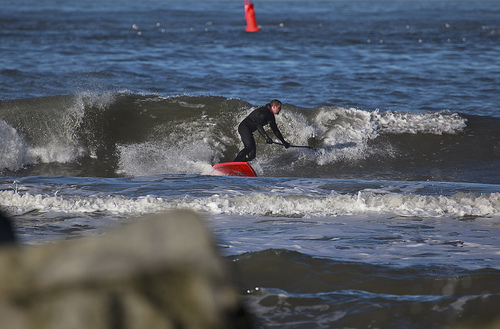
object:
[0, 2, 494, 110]
water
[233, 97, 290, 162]
surfer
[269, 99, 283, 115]
head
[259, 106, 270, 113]
shoulder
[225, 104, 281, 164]
surfer suit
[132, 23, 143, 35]
birds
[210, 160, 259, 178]
surfboard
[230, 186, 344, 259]
water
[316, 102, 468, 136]
cap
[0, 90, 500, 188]
wave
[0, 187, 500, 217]
foam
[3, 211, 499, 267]
surface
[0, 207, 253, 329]
rock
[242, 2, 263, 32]
bouy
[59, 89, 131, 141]
curl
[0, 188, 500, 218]
wave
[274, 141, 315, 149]
pole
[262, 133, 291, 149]
hand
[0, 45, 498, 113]
ripples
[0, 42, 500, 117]
surface